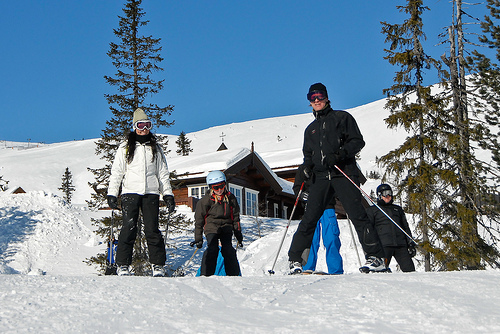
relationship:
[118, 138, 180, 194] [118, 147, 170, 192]
woman wearing jacket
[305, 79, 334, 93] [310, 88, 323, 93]
man wearing hat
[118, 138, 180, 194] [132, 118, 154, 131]
woman wearing goggles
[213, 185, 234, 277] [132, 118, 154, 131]
kid has goggles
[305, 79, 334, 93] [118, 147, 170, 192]
man wearing jacket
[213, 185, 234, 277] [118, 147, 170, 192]
kid wearing jacket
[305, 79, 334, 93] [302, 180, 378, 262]
man wearing pants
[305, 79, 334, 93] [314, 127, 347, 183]
man wearing black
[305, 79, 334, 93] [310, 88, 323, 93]
man has hat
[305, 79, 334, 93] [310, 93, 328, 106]
man wearing sunglasses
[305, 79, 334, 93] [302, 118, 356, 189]
man wearing coat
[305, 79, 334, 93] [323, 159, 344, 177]
man has gloves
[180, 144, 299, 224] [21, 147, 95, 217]
building on hill